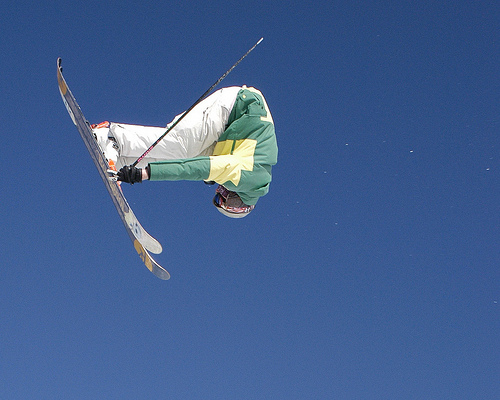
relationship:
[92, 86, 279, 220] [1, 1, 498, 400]
man in air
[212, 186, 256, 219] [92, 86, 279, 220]
head of man